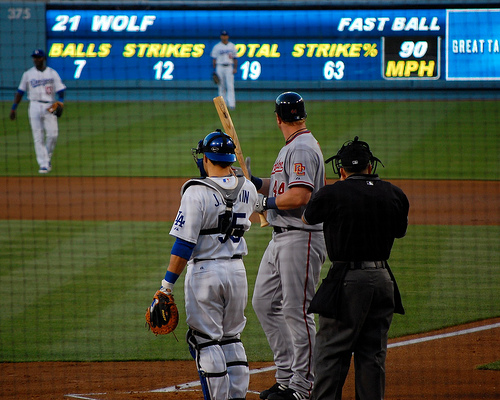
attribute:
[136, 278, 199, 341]
carton — red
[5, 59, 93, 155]
panda — white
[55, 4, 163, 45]
wolf — 21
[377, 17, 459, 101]
sign — 90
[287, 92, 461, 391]
umpire — standing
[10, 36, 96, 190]
catcher — standing, la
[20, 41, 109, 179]
player — baseball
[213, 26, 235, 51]
man — wearing, outfield, playing, holding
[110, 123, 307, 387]
he — wearing, holding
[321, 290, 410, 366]
pant — grey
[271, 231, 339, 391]
stripe — red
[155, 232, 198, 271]
shirt — blue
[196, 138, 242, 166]
helmet — blue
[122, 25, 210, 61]
word — yellow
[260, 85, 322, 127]
helmet — black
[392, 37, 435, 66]
number — white